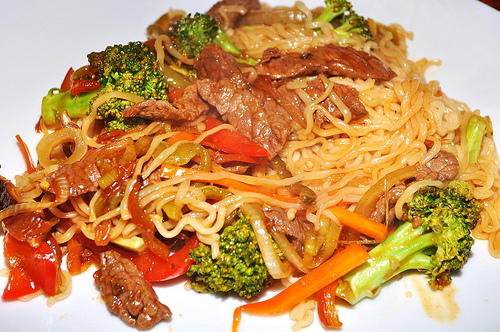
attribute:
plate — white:
[2, 2, 498, 331]